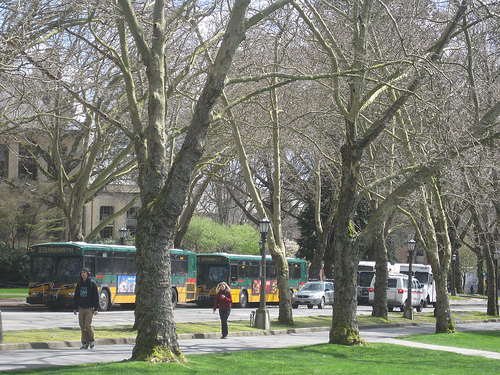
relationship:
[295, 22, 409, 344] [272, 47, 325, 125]
tree has no leaves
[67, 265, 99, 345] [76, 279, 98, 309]
man has jacket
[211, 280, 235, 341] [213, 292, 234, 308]
people has jacket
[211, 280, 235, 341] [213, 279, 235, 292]
people has hair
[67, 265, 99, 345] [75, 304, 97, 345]
man has pants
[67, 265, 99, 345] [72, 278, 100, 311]
man has jacket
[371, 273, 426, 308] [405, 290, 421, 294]
van has stripe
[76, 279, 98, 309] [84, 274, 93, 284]
jacket has hoodie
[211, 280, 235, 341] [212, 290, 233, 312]
people has jacket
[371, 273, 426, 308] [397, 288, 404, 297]
van has light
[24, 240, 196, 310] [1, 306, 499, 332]
bus on street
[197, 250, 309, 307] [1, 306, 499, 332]
bus on street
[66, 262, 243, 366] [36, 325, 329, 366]
people on sidewalk